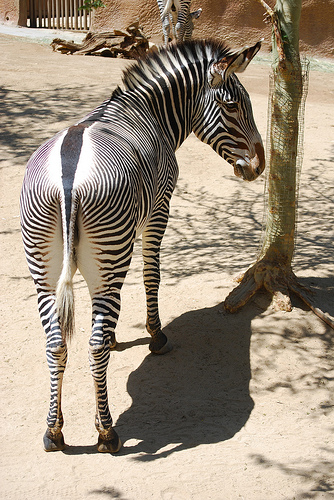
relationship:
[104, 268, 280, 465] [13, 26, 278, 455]
shadow of zebra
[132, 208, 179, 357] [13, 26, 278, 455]
leg of zebra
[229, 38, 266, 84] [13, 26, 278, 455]
ear of zebra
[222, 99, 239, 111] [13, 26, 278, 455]
eye of zebra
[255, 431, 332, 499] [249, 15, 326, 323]
shadow of trees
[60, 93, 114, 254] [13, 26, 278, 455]
stripe of zebra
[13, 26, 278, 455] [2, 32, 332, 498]
zebra standing on ground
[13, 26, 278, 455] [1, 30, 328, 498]
zebra standing on dirt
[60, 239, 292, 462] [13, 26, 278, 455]
shadow from zebra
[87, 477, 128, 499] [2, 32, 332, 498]
shadow on ground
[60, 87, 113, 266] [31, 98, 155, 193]
stripe on back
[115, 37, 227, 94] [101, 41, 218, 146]
hair along neck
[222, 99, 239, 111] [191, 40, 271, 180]
eye on side of head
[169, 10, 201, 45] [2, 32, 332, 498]
head bent down to ground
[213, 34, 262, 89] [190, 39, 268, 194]
ears sticking off top of head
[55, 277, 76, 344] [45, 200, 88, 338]
hair on bottom of tail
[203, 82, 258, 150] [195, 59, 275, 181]
stripes on face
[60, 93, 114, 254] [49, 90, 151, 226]
stripe running down back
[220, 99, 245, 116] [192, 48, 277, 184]
eye on side of face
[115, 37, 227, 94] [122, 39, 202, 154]
hair running down neck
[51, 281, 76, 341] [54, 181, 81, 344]
hair on end of tail